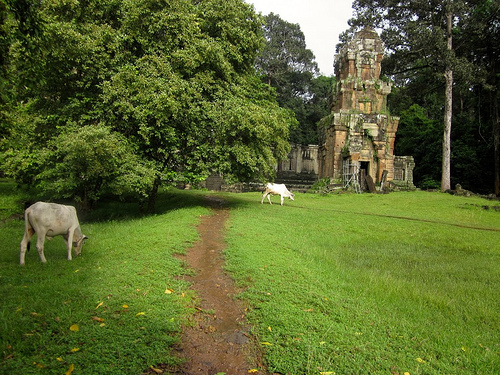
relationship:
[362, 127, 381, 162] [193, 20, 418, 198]
moss on structure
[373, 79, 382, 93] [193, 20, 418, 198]
moss on structure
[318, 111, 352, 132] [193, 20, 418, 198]
moss on structure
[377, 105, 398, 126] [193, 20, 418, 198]
moss on structure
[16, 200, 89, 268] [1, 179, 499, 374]
cow on grass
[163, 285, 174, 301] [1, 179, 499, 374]
leaf in grass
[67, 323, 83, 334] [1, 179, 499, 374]
leaf in grass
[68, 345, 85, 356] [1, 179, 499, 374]
leaf in grass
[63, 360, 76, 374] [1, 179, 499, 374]
leaf in grass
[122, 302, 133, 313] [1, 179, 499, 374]
leaf in grass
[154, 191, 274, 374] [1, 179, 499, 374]
path in grass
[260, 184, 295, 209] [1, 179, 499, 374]
cow on grass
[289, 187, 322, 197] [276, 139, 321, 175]
step leads to building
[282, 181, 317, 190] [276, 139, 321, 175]
step leads to building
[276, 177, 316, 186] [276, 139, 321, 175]
step leads to building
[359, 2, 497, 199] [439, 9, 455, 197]
tree has trunk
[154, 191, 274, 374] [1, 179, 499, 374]
path divides grass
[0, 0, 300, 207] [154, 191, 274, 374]
tree left of path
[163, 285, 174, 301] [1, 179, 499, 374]
leaf on grass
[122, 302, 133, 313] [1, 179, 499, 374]
leaf on grass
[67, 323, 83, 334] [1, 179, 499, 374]
leaf on grass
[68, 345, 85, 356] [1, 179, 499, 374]
leaf on grass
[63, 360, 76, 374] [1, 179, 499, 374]
leaf on grass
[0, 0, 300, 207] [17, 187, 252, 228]
tree casts shadow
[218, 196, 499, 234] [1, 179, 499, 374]
shadow on grass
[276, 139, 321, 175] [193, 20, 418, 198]
building behind structure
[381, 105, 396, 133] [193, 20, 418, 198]
ivy on structure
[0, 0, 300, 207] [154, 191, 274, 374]
tree next to path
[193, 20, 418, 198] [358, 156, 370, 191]
structure has door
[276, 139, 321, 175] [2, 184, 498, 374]
building in field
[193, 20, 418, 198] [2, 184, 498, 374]
structure in field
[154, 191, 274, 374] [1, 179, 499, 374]
path goes through grass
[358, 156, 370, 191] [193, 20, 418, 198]
door front of structure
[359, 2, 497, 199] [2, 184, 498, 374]
tree in field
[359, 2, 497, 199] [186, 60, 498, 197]
tree in background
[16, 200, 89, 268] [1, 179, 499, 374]
cow looking at grass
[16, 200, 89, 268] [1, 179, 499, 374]
cow eats grass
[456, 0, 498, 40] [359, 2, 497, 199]
leaves are on tree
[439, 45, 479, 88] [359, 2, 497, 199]
leaves are on tree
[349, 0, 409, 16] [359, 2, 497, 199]
leaves are on tree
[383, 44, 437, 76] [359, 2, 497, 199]
leaves are on tree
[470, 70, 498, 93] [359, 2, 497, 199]
leaves are on tree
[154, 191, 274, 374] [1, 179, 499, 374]
path in center of grass